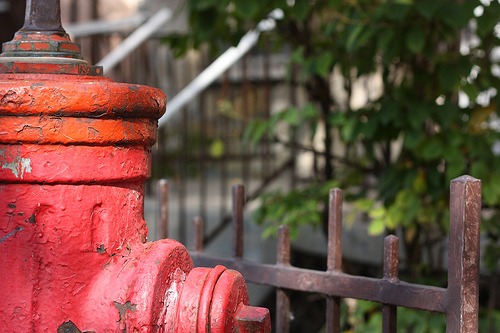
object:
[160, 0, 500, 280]
green tree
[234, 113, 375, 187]
tree branch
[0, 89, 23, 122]
paint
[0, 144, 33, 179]
scratch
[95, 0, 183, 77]
railing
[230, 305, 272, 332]
bolt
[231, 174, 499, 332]
gate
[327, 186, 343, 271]
bar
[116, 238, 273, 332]
outlet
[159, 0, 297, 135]
rail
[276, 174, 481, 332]
iron gate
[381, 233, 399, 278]
metal bar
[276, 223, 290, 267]
metal bar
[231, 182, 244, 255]
metal bar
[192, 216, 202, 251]
metal bar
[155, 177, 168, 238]
metal bar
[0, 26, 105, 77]
spot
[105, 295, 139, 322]
paint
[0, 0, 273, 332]
fire hydrant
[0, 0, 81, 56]
top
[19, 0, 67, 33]
bolt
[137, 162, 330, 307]
steps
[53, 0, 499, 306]
building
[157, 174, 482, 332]
fence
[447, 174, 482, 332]
bar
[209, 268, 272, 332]
cap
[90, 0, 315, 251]
stairs